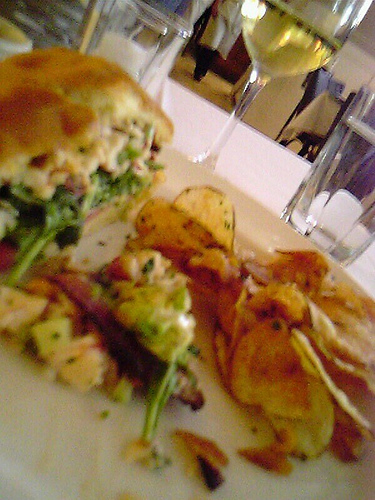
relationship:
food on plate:
[8, 52, 341, 386] [159, 149, 313, 271]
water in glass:
[292, 117, 374, 264] [278, 121, 373, 263]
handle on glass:
[190, 67, 270, 168] [189, 0, 374, 180]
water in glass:
[292, 117, 374, 264] [282, 84, 373, 272]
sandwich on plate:
[1, 48, 176, 276] [4, 50, 374, 498]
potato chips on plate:
[167, 188, 366, 461] [3, 137, 373, 499]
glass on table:
[282, 84, 373, 272] [4, 16, 369, 498]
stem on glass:
[200, 63, 272, 170] [194, 0, 357, 204]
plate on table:
[3, 137, 373, 499] [163, 74, 374, 296]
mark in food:
[269, 321, 284, 333] [0, 0, 375, 500]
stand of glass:
[191, 71, 269, 174] [240, 1, 371, 77]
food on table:
[0, 0, 375, 500] [173, 98, 374, 295]